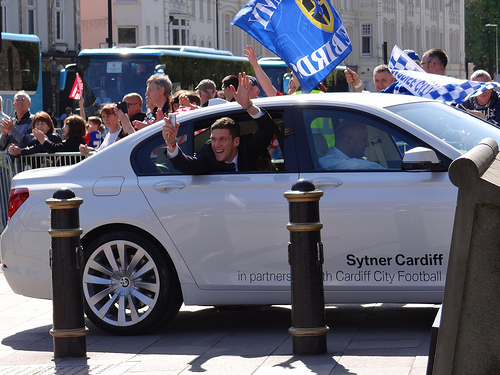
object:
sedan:
[1, 93, 500, 335]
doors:
[136, 104, 306, 291]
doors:
[301, 102, 460, 292]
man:
[162, 71, 289, 176]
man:
[318, 119, 389, 171]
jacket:
[166, 110, 281, 174]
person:
[243, 43, 303, 96]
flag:
[275, 0, 354, 94]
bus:
[73, 44, 163, 118]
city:
[1, 2, 497, 374]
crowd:
[3, 59, 500, 146]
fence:
[3, 153, 95, 236]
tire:
[78, 227, 184, 336]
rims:
[81, 239, 160, 327]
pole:
[46, 187, 91, 365]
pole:
[283, 179, 331, 356]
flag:
[69, 73, 83, 99]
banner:
[386, 45, 500, 106]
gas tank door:
[90, 174, 125, 198]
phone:
[166, 112, 176, 128]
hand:
[160, 118, 181, 148]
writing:
[236, 252, 446, 284]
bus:
[0, 32, 44, 120]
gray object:
[433, 138, 498, 374]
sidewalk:
[2, 360, 497, 374]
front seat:
[310, 128, 332, 158]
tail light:
[7, 187, 29, 220]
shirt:
[320, 146, 397, 173]